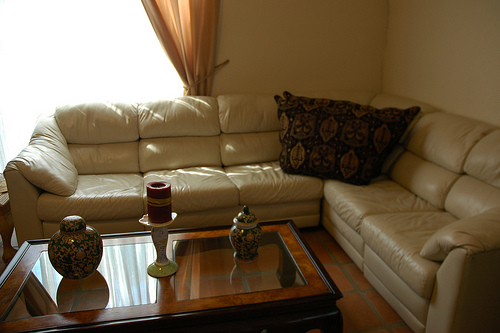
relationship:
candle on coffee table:
[140, 178, 182, 278] [1, 217, 345, 329]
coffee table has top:
[1, 217, 345, 329] [7, 226, 308, 322]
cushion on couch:
[268, 83, 425, 181] [7, 92, 492, 332]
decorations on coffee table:
[45, 214, 108, 277] [1, 217, 345, 329]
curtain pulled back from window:
[140, 1, 229, 99] [9, 1, 189, 102]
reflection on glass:
[47, 270, 117, 325] [3, 227, 305, 320]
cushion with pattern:
[268, 83, 425, 181] [282, 101, 394, 170]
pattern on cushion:
[282, 101, 394, 170] [268, 83, 425, 181]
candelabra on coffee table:
[139, 213, 179, 276] [1, 217, 345, 329]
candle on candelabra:
[144, 180, 173, 226] [139, 213, 179, 276]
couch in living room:
[7, 92, 492, 332] [3, 11, 498, 326]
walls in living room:
[207, 1, 498, 125] [3, 11, 498, 326]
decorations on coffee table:
[45, 214, 108, 277] [1, 213, 345, 329]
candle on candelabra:
[140, 178, 182, 278] [139, 213, 179, 276]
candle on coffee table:
[140, 178, 182, 278] [1, 213, 345, 329]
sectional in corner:
[3, 75, 499, 327] [213, 3, 499, 332]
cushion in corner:
[268, 83, 425, 181] [269, 83, 422, 179]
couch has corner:
[7, 92, 492, 332] [213, 3, 499, 332]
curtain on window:
[140, 1, 229, 99] [9, 1, 189, 102]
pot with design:
[230, 202, 259, 261] [230, 212, 260, 258]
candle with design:
[140, 178, 182, 278] [143, 198, 174, 210]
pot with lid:
[230, 202, 259, 261] [230, 204, 264, 224]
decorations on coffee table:
[45, 173, 270, 286] [1, 213, 345, 329]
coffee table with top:
[1, 213, 345, 329] [7, 226, 308, 322]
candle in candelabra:
[140, 178, 182, 278] [137, 212, 179, 283]